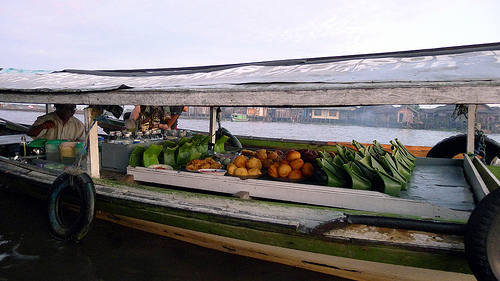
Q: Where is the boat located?
A: Water.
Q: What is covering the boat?
A: Roof.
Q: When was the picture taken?
A: Daytime.